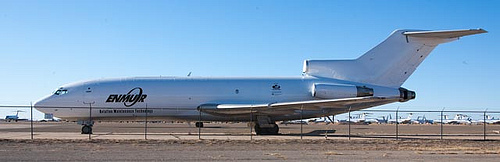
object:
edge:
[198, 76, 302, 79]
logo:
[104, 87, 148, 107]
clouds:
[16, 25, 103, 70]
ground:
[385, 57, 391, 85]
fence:
[0, 105, 498, 143]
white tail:
[301, 25, 486, 88]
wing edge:
[399, 27, 485, 38]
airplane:
[30, 27, 488, 135]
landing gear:
[77, 120, 94, 142]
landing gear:
[255, 118, 280, 135]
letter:
[99, 109, 154, 113]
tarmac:
[0, 122, 500, 162]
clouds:
[191, 41, 281, 76]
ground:
[3, 120, 498, 160]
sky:
[0, 0, 498, 123]